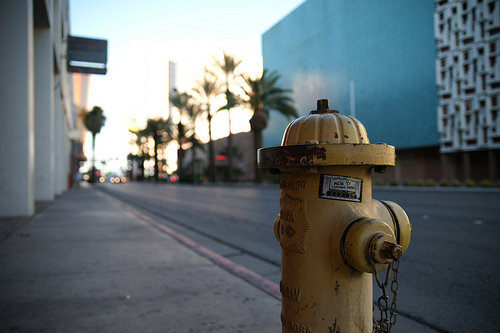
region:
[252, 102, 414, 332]
the hydant is yellow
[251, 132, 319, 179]
rust is on the hydrant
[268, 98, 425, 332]
the hydrant is made of metal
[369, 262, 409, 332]
the chain is iron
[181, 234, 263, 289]
the curb is brown red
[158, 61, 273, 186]
palmtrees are along the road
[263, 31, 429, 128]
the wall is blue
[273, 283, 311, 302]
letters are on the hydrant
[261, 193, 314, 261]
logo is on the hydrant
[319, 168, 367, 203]
the sticker is white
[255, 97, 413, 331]
yellow fire hydrant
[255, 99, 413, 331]
the fire hydrant is yellow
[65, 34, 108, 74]
the sign on the building is black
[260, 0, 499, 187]
the building is blue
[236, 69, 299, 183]
there is a tree in front of the blue building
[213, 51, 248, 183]
there is a tree in front of the blue building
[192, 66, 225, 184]
there is a tree in front of the blue building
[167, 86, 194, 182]
there is a tree in front of the blue building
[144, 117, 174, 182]
there is a tree in front of the blue building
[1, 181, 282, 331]
the sidewalk is grey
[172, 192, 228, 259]
this is a road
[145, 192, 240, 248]
the road is tarmacked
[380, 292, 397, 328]
this is a chain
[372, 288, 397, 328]
the chain is mettalic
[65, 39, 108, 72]
this is a billboard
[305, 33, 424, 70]
this is a wall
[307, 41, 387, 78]
the wall is blue in colour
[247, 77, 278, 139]
this is a tree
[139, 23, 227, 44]
this is the sky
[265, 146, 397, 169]
this part is cylindrical in shape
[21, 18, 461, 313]
a fire hydrant on a street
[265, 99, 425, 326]
the hydrant is yellow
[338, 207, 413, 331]
a chain on the hydrant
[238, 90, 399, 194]
the paint is peeling off of the hydrant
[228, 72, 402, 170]
this is the top of the hydrant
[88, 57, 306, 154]
palm trees along the street area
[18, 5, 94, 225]
businesses on the street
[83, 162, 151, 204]
cars in the distance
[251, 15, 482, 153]
a blue building next to the street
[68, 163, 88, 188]
a blurry man walking in the distance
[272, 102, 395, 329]
yellow fire hydrant near road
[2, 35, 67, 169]
white pillars of building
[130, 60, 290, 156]
palm trees growing by road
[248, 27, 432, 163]
blue side of building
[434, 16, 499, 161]
white design on building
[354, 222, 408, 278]
yellow cap on hydrant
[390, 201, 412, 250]
yellow cap on hydrant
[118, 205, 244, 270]
red curb of streetside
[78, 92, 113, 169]
palm trees on left of road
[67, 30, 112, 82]
black sign on side of building